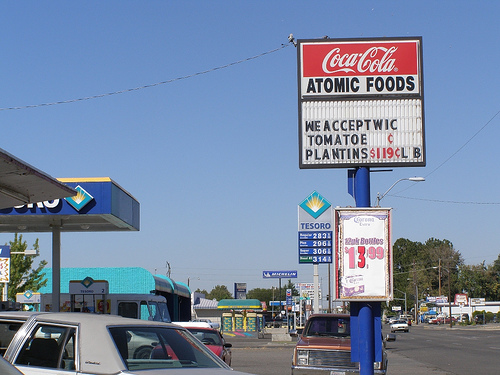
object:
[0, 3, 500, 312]
sky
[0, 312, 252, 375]
car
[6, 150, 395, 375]
station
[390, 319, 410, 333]
car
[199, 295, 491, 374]
street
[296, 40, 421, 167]
sign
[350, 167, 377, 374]
pole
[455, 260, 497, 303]
tree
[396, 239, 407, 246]
leaves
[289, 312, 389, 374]
car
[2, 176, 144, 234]
awning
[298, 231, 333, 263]
prices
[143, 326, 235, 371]
car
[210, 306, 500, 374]
road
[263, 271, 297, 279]
sign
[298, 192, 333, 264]
sign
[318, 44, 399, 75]
logo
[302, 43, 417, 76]
rectangle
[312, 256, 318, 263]
numbers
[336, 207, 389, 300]
sign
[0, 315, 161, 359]
car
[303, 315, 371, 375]
front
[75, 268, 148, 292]
side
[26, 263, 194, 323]
building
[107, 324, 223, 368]
back window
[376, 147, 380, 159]
numbers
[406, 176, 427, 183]
street light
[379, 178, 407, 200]
pole